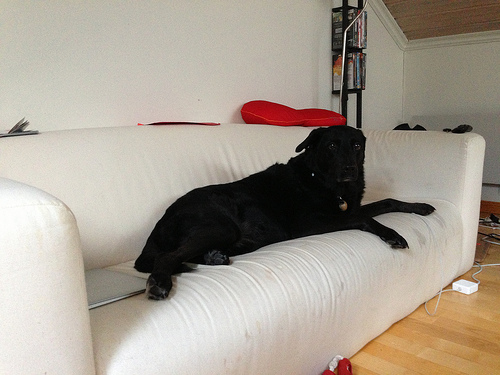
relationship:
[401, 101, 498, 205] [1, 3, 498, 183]
shadow on wall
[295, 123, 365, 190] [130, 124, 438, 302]
head connected to black dog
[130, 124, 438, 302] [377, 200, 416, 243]
black dog has paws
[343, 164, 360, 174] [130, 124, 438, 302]
nose of black dog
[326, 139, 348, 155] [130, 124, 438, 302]
eye of black dog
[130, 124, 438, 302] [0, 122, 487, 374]
black dog on couch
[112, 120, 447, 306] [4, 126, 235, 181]
black dog laying on a couch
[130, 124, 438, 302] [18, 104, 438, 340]
black dog laying on a couch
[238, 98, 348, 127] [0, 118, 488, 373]
red pillow on a couch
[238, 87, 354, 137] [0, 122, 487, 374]
red pillow on a couch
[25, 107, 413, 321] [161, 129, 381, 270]
couch with a dog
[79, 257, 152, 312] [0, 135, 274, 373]
laptop on couch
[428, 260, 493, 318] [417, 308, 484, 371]
wires on floor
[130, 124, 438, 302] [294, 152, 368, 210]
black dog wearing a collar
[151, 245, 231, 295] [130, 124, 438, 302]
feet of black dog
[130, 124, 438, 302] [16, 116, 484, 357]
black dog laying on a couch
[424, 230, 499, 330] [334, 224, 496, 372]
power cord on floor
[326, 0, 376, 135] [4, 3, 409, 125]
shelf on wall